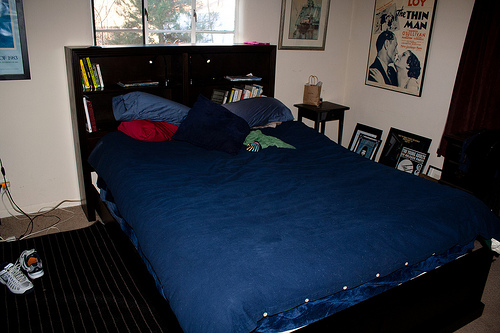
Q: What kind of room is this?
A: Bedroom.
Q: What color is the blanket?
A: Blue.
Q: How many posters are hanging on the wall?
A: Three.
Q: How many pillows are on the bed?
A: 4.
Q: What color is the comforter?
A: Blue.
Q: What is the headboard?
A: Bookshelf.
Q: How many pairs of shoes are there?
A: 1.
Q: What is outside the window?
A: Tree.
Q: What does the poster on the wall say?
A: Thin Man.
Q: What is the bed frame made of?
A: Wood.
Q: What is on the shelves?
A: Books.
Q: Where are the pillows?
A: At head of bed.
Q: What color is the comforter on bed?
A: Blue.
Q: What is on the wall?
A: Poster of old movie.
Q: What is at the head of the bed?
A: Headboard with shelves of books.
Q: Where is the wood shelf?
A: In front of the wall.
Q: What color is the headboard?
A: Dark brown.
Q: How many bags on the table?
A: One.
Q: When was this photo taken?
A: Day time.